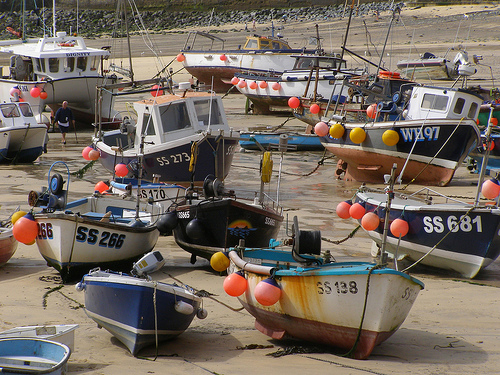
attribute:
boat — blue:
[82, 265, 203, 359]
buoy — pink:
[254, 283, 283, 312]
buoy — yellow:
[208, 249, 230, 275]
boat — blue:
[315, 79, 483, 187]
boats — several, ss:
[0, 31, 500, 373]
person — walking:
[53, 97, 81, 148]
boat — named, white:
[227, 227, 426, 357]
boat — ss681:
[343, 180, 499, 281]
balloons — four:
[335, 200, 412, 239]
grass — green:
[49, 1, 342, 11]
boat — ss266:
[15, 176, 158, 281]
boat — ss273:
[90, 93, 240, 189]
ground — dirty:
[0, 31, 498, 373]